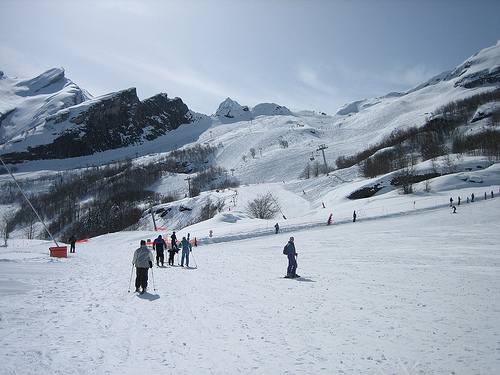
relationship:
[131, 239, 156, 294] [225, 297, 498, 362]
skier in snow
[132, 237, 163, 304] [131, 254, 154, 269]
skier in white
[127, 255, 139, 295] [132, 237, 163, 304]
pole with skier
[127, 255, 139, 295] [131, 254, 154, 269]
pole by white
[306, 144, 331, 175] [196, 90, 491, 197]
lift by mountain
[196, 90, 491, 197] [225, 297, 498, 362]
mountain has snow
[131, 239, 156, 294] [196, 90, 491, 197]
skier by mountain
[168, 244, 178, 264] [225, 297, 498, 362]
kid by snow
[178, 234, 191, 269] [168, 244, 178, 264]
woman by kid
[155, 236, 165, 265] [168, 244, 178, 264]
man by kid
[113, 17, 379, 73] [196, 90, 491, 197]
sky by mountain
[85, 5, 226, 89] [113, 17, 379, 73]
clouds in sky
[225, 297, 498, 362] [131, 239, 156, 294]
snow by skier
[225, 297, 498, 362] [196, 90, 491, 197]
snow on mountain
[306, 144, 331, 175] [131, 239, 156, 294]
lift by skier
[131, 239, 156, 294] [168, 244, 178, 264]
skier with kid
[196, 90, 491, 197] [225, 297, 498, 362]
mountain with snow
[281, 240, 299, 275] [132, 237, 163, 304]
adult with skier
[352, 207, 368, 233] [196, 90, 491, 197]
skier on mountain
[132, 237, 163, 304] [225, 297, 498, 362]
skier in snow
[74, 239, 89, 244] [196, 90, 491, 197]
fence by mountain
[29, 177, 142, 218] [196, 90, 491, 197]
trees by mountain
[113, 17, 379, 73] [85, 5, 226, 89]
sky has clouds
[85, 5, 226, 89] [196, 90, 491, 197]
clouds by mountain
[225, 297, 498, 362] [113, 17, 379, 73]
snow by sky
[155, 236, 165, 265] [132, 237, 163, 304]
man by skier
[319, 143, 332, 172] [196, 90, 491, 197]
stick by mountain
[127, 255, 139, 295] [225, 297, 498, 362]
pole by snow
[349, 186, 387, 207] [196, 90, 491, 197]
rock by mountain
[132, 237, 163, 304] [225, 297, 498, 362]
skier by snow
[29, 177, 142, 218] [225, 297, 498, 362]
trees in snow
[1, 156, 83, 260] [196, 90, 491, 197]
support by mountain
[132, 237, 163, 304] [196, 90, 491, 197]
skier by mountain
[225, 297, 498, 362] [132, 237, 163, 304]
snow by skier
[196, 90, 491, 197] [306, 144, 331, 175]
mountain by lift